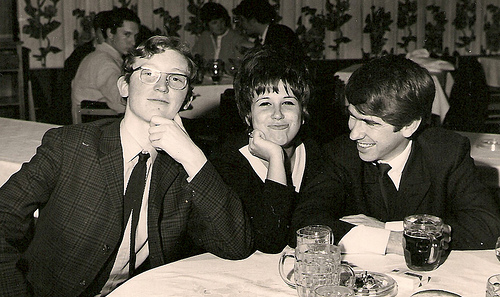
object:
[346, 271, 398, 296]
ashtray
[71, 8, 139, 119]
people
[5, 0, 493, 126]
background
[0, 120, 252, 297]
suit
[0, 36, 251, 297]
man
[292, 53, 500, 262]
man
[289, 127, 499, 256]
suit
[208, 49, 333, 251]
people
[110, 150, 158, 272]
tie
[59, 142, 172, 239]
chest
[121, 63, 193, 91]
glasses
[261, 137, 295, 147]
chin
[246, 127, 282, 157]
hand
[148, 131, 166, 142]
fingers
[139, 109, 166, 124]
chin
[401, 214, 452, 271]
glass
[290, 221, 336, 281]
glassware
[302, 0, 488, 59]
curtains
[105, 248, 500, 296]
tablecloth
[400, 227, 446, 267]
beverage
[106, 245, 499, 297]
table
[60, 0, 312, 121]
group